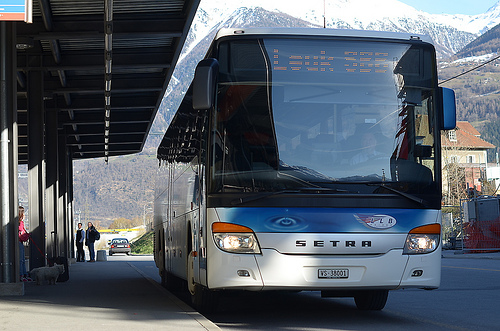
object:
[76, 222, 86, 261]
people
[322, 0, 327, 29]
antenna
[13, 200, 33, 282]
person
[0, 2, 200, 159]
roof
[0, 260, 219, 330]
platform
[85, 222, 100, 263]
people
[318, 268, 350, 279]
tag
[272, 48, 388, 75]
sing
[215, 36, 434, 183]
windshield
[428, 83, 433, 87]
ground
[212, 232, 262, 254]
headlight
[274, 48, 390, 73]
letters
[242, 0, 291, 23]
snow mountains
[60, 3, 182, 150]
sky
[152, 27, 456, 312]
bus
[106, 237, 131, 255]
car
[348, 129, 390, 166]
driver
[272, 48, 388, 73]
sign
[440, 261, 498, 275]
paint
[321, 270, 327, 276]
letters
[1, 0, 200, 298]
building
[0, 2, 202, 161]
awning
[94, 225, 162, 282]
street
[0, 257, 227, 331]
sidewalk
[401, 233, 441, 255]
headlight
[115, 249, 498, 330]
road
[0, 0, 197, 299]
bus terminal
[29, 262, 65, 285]
dog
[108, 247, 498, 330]
street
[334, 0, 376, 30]
snow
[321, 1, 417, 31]
mountains